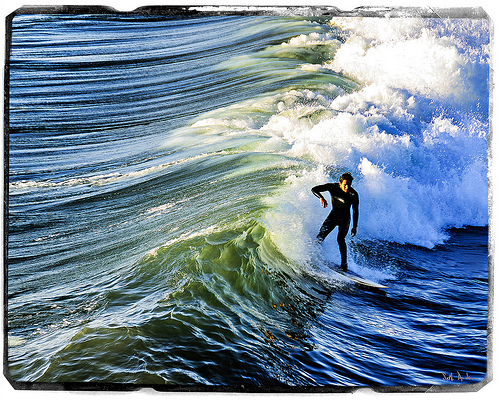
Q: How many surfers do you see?
A: One.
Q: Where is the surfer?
A: Ocean.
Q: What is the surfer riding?
A: Wave.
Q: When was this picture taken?
A: Daytime.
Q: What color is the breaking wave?
A: White.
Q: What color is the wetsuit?
A: Black.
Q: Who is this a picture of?
A: Surfer.